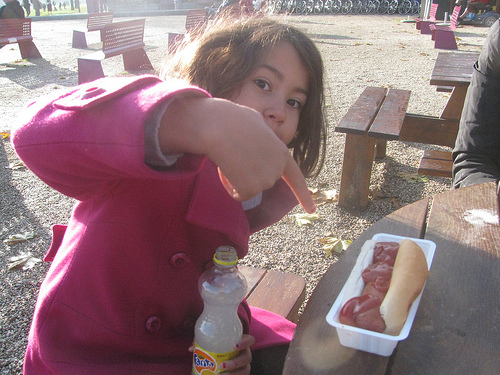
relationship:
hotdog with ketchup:
[337, 238, 432, 336] [341, 241, 397, 321]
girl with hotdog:
[11, 16, 328, 374] [337, 238, 432, 336]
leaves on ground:
[320, 235, 354, 260] [224, 14, 499, 318]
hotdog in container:
[337, 238, 432, 336] [324, 233, 438, 359]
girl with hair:
[11, 16, 328, 374] [154, 12, 329, 181]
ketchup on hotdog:
[341, 241, 397, 321] [337, 238, 432, 336]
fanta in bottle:
[192, 246, 248, 374] [191, 245, 248, 374]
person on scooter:
[458, 0, 490, 20] [454, 0, 500, 27]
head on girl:
[184, 15, 330, 182] [11, 16, 328, 374]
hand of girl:
[159, 95, 319, 215] [11, 16, 328, 374]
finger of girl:
[283, 149, 317, 215] [11, 16, 328, 374]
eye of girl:
[253, 79, 272, 92] [11, 16, 328, 374]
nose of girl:
[262, 92, 288, 126] [11, 16, 328, 374]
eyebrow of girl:
[255, 64, 284, 82] [11, 16, 328, 374]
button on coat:
[144, 316, 163, 334] [14, 75, 312, 374]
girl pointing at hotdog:
[11, 16, 328, 374] [337, 238, 432, 336]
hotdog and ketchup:
[337, 238, 432, 336] [341, 241, 397, 321]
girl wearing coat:
[11, 16, 328, 374] [14, 75, 312, 374]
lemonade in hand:
[191, 245, 248, 374] [187, 334, 256, 375]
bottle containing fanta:
[191, 245, 248, 374] [190, 354, 217, 368]